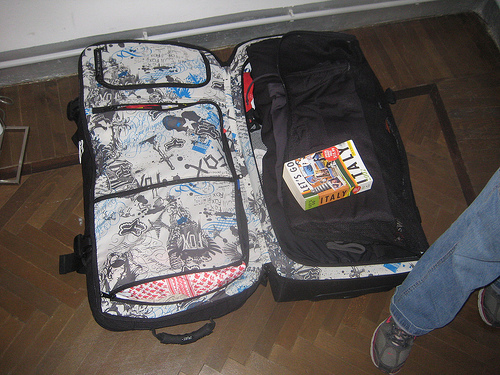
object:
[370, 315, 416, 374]
foot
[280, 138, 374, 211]
book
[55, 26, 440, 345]
suitcase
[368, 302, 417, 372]
shoe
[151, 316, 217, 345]
handle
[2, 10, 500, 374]
floor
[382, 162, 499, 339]
jeans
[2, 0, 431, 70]
pipe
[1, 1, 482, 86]
wall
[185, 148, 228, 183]
logo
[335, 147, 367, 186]
title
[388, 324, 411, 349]
laces